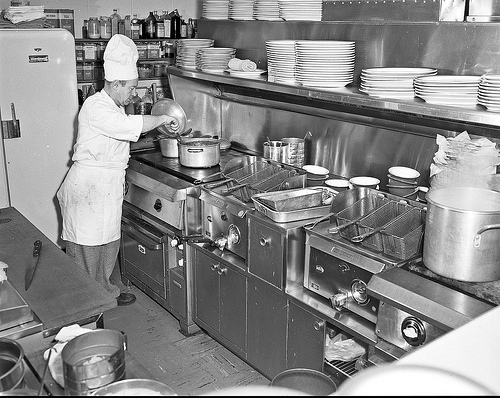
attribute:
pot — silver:
[176, 136, 221, 168]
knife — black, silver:
[24, 239, 44, 291]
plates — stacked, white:
[296, 39, 356, 89]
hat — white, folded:
[102, 33, 139, 80]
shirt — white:
[69, 89, 144, 168]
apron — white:
[55, 162, 126, 246]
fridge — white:
[0, 27, 76, 249]